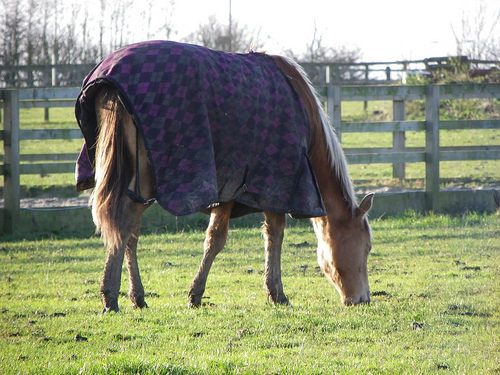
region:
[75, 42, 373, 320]
a horse covered in fabric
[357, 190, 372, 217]
a horse's ear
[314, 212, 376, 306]
a horse's head as it eats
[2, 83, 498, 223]
a long wooden fence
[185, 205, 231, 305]
leg of a horse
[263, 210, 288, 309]
leg of a horse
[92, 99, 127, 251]
the tail of a horse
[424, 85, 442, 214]
a thick wooden pole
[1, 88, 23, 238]
a square wooden post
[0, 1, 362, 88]
trees in the distance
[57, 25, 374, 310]
A horse with a blanket on his back.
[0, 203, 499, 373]
lots of green grass in the pasture.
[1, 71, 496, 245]
A wooden fence to keep the horse contained.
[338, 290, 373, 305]
The horse's mouth is eating the grass.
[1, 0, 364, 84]
Many trees with no leaves, must be fall.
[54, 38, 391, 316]
A hungry horse stands in the field.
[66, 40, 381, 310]
A brown horse enjoys it's time out in the fresh air.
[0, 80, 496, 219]
An old wood fence separates the pastures.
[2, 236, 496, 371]
lots of grass growing on the ground.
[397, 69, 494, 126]
A mound of dirt with grass on it.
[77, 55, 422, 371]
This is a picture of a horse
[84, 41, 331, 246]
This is a picture of a blanket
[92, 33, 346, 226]
The blanket is argyle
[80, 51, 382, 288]
The blanket is purple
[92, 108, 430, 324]
The horse is light brown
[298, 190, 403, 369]
The horse is eating grass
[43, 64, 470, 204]
This is a picture of a fence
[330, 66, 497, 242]
This is a wooden fence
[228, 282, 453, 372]
This is a picture of short grass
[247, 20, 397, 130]
The sky is cloudy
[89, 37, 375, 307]
big brown horse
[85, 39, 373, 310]
brown horse with head down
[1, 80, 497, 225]
gray wooden fence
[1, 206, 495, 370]
small green grass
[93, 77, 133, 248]
brown hairy pony tail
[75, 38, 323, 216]
black purple and gray blanket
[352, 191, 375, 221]
small left ear of horse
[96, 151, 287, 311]
four legs of big horse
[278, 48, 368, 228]
white hair in back of horse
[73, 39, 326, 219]
black purple and gray blanket on horse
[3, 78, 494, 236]
Wooden fence in a field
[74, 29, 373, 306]
Brown horse eating grass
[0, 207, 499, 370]
Grassy field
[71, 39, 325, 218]
Checkered purple and black blanket on a horse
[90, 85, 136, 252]
Horse's tail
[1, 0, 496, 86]
Leafless trees in the background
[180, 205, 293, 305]
Horse's front legs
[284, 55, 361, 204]
White horse's mane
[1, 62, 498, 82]
Wooden fence in the far background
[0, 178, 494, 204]
Gravel walkway between two fields